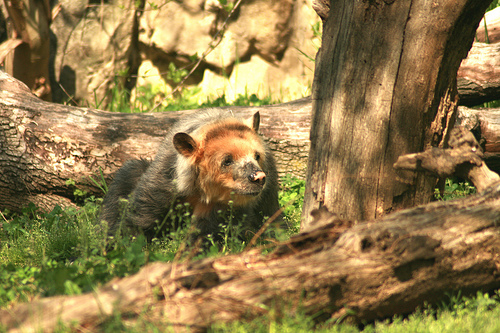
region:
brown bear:
[140, 80, 275, 227]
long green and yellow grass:
[116, 251, 135, 270]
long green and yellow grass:
[412, 315, 433, 331]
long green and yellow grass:
[58, 215, 78, 245]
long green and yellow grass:
[10, 240, 27, 254]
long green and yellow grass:
[449, 308, 484, 329]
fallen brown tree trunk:
[1, 180, 499, 330]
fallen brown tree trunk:
[1, 70, 316, 215]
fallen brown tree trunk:
[454, 40, 499, 99]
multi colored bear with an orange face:
[96, 108, 288, 249]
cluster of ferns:
[3, 204, 109, 264]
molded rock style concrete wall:
[1, 0, 323, 110]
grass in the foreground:
[1, 280, 498, 332]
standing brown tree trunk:
[295, 0, 490, 232]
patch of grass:
[1, 173, 308, 306]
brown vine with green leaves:
[162, 0, 242, 108]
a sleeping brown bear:
[110, 111, 282, 253]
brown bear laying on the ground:
[102, 108, 277, 250]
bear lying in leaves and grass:
[103, 105, 278, 260]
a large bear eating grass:
[103, 108, 278, 268]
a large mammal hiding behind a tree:
[100, 114, 342, 261]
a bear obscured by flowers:
[70, 113, 268, 260]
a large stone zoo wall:
[10, 0, 307, 107]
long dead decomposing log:
[2, 207, 499, 331]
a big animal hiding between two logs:
[102, 93, 280, 331]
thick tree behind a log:
[312, 0, 474, 327]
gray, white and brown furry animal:
[98, 103, 280, 248]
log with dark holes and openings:
[7, 189, 494, 323]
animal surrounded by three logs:
[30, 95, 356, 285]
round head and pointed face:
[189, 120, 269, 209]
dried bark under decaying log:
[4, 108, 70, 194]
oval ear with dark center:
[170, 132, 198, 158]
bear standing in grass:
[87, 101, 298, 262]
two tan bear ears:
[151, 101, 276, 161]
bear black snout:
[235, 163, 269, 190]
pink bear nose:
[249, 168, 268, 187]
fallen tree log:
[0, 111, 499, 331]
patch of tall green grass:
[0, 161, 315, 301]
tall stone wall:
[2, 0, 499, 120]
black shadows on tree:
[328, 32, 398, 191]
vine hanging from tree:
[52, 1, 239, 109]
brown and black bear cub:
[98, 110, 281, 237]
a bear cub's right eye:
[219, 154, 233, 169]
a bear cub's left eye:
[253, 152, 263, 163]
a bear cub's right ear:
[173, 132, 199, 159]